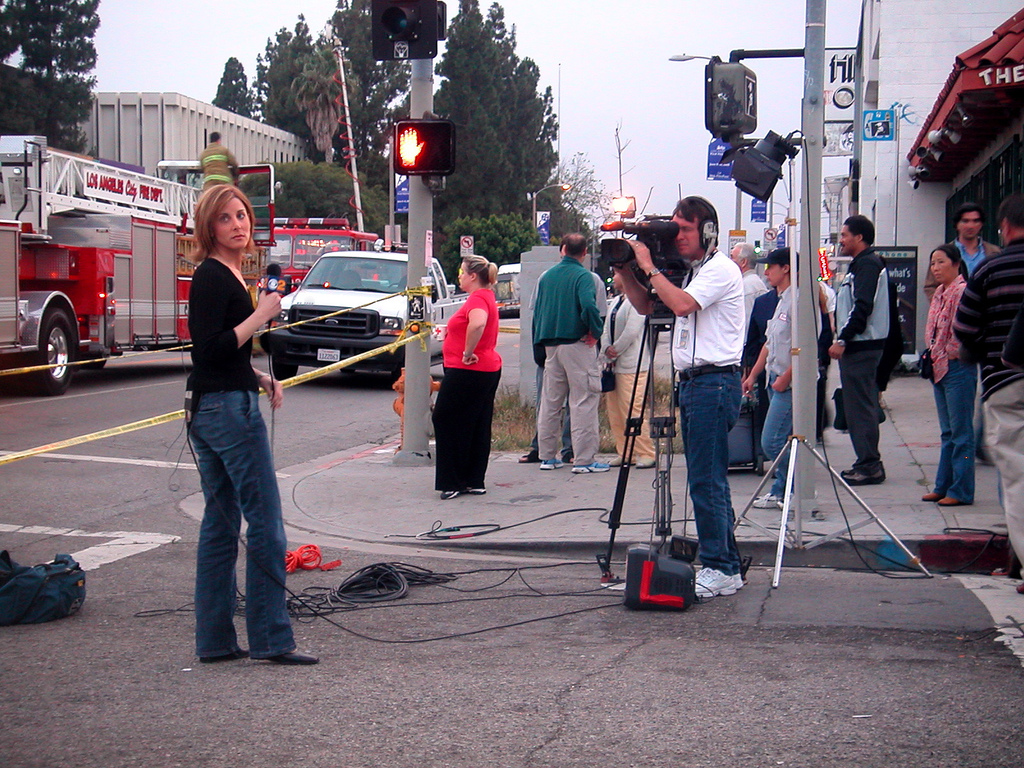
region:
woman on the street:
[190, 188, 321, 653]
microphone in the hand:
[257, 262, 281, 316]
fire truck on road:
[4, 135, 198, 386]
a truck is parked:
[261, 259, 464, 380]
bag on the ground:
[0, 548, 87, 626]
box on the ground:
[626, 545, 693, 609]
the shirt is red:
[440, 290, 501, 370]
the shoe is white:
[696, 568, 738, 594]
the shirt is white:
[669, 252, 742, 366]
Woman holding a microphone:
[184, 173, 315, 668]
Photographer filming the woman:
[590, 193, 749, 601]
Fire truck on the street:
[3, 127, 213, 399]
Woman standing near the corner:
[427, 246, 503, 504]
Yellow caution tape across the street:
[0, 286, 437, 476]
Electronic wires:
[290, 476, 986, 664]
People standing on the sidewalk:
[429, 195, 1006, 509]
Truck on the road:
[276, 241, 476, 387]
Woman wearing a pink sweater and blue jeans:
[921, 239, 975, 508]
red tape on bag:
[624, 545, 710, 628]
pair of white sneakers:
[691, 535, 756, 641]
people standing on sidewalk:
[451, 190, 935, 505]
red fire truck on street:
[0, 119, 270, 358]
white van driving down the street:
[272, 236, 526, 395]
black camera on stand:
[572, 190, 721, 522]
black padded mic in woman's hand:
[249, 250, 327, 355]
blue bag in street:
[14, 523, 100, 641]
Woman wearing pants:
[177, 384, 315, 672]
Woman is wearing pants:
[168, 373, 312, 667]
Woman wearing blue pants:
[171, 377, 312, 673]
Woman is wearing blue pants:
[182, 368, 310, 664]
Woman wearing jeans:
[171, 375, 317, 655]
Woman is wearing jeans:
[179, 378, 312, 667]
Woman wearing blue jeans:
[178, 367, 316, 662]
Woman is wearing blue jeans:
[171, 359, 314, 658]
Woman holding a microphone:
[253, 247, 298, 339]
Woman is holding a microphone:
[253, 251, 301, 338]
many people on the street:
[147, 101, 954, 514]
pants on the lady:
[123, 380, 333, 649]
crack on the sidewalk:
[489, 619, 661, 766]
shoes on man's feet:
[663, 516, 774, 621]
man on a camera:
[536, 156, 794, 521]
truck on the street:
[255, 214, 497, 414]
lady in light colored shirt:
[392, 219, 536, 466]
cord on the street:
[319, 511, 534, 689]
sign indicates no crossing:
[385, 110, 459, 186]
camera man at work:
[600, 197, 741, 609]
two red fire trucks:
[8, 156, 397, 360]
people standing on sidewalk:
[433, 205, 1019, 519]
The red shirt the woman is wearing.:
[441, 295, 500, 376]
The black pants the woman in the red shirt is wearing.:
[433, 370, 482, 489]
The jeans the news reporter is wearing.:
[187, 380, 289, 653]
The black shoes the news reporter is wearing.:
[200, 642, 324, 668]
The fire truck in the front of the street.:
[4, 126, 220, 383]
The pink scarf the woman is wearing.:
[922, 283, 970, 375]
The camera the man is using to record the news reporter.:
[596, 205, 696, 314]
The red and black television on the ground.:
[615, 547, 696, 611]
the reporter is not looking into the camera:
[175, 177, 331, 680]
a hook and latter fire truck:
[0, 121, 268, 401]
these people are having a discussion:
[526, 228, 664, 479]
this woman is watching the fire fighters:
[426, 244, 507, 501]